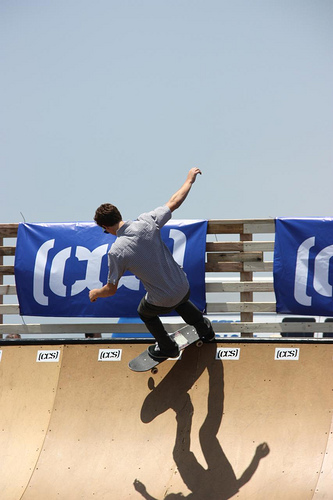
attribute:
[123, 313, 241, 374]
skateboard — black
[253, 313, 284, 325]
snow — white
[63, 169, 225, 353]
man — skateboarding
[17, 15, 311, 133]
sky — blue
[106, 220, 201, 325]
shirt — blue, grey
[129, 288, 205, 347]
jeans — black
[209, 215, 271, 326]
fence — wooden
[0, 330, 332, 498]
halfpipe — wooded, wooden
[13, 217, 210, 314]
banner — blue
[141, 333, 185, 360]
shoes — black